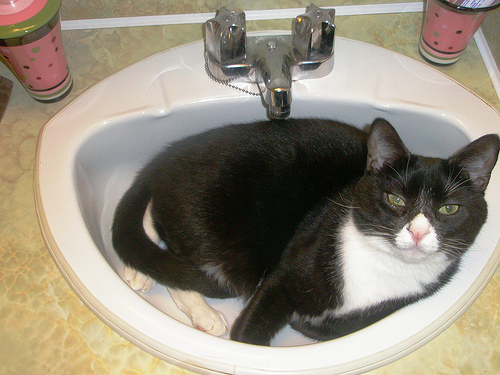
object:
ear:
[365, 117, 411, 176]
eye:
[387, 193, 406, 207]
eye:
[438, 204, 460, 215]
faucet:
[203, 3, 335, 120]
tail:
[110, 150, 242, 299]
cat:
[111, 116, 499, 346]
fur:
[324, 234, 389, 309]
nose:
[409, 214, 431, 247]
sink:
[72, 97, 472, 348]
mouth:
[394, 243, 439, 255]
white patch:
[334, 214, 452, 316]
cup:
[417, 0, 500, 67]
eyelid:
[352, 155, 487, 261]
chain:
[204, 55, 262, 97]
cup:
[0, 0, 74, 104]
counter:
[0, 295, 58, 375]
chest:
[324, 215, 454, 310]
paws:
[193, 310, 229, 337]